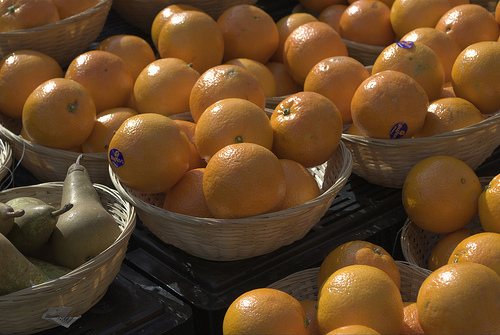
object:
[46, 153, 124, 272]
pear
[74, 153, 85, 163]
stem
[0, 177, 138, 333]
bowl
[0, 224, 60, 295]
pear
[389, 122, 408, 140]
sticker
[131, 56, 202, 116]
orange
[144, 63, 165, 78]
sunlight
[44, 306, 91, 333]
label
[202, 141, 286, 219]
orange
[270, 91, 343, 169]
orange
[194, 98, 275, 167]
orange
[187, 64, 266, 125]
orange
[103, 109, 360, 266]
basket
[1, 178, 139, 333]
basket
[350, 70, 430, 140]
orange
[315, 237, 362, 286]
shadow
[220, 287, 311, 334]
orange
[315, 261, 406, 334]
orange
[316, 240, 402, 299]
orange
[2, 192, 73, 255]
pear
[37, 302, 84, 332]
paper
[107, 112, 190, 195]
orange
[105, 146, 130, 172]
sticker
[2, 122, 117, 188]
basket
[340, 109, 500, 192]
basket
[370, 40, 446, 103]
orange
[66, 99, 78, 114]
stem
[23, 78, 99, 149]
orange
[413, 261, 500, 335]
oranges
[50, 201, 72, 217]
stem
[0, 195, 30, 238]
pear